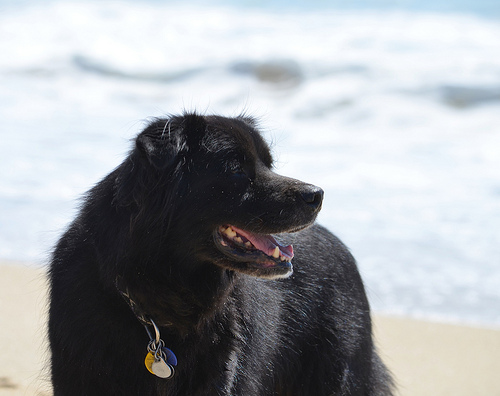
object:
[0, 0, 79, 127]
cloud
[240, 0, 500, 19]
sky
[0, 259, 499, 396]
ground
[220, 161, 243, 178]
eye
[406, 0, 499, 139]
clouds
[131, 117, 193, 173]
ear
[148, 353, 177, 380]
tag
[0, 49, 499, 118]
ocean wave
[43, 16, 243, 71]
clouds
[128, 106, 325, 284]
head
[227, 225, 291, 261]
tongue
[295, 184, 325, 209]
nose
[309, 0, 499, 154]
clouds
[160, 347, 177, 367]
charms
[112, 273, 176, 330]
chain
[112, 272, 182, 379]
collar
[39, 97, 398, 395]
dog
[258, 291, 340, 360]
fur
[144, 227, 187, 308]
fur